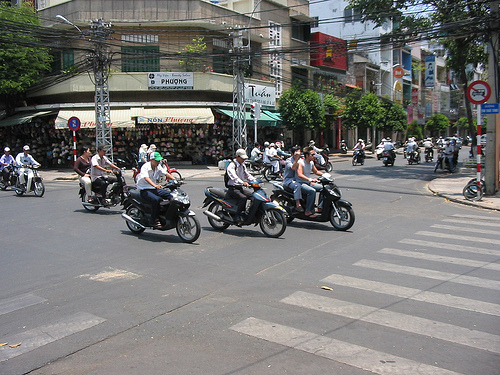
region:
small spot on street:
[66, 245, 174, 310]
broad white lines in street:
[215, 301, 342, 373]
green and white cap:
[145, 148, 177, 167]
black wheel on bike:
[172, 212, 213, 247]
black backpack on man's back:
[217, 158, 247, 181]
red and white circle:
[460, 70, 498, 128]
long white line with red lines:
[459, 97, 493, 187]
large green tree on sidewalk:
[284, 90, 313, 145]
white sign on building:
[125, 58, 224, 99]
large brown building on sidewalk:
[67, 3, 291, 193]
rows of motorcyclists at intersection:
[37, 95, 459, 281]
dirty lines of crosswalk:
[285, 195, 482, 362]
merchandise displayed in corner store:
[60, 102, 260, 167]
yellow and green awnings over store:
[45, 102, 275, 122]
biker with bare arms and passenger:
[276, 137, 361, 242]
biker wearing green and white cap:
[120, 145, 200, 241]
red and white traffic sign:
[437, 62, 492, 198]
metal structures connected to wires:
[41, 10, 271, 170]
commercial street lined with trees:
[276, 15, 461, 145]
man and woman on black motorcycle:
[65, 136, 130, 216]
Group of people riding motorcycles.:
[1, 138, 357, 245]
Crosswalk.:
[224, 205, 499, 372]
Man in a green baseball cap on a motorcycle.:
[124, 148, 200, 242]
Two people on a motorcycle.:
[272, 141, 356, 233]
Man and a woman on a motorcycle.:
[70, 142, 136, 214]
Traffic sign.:
[467, 76, 490, 199]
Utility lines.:
[1, 0, 498, 101]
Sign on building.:
[146, 68, 193, 91]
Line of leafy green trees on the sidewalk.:
[276, 81, 477, 159]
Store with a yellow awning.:
[2, 108, 297, 165]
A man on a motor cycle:
[118, 150, 199, 245]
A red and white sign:
[465, 78, 492, 205]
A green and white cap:
[150, 148, 163, 162]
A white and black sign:
[142, 69, 194, 88]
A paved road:
[2, 288, 497, 374]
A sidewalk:
[440, 176, 461, 191]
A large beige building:
[0, 0, 310, 167]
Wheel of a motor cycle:
[255, 208, 286, 237]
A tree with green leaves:
[274, 78, 325, 154]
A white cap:
[235, 148, 248, 160]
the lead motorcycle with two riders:
[270, 147, 356, 232]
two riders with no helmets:
[272, 146, 354, 229]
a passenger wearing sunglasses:
[277, 146, 302, 221]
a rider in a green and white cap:
[119, 150, 199, 244]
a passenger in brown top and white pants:
[71, 142, 95, 210]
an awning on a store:
[136, 99, 222, 132]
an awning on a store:
[55, 107, 136, 133]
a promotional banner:
[233, 80, 286, 111]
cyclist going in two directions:
[342, 127, 482, 177]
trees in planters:
[268, 87, 490, 154]